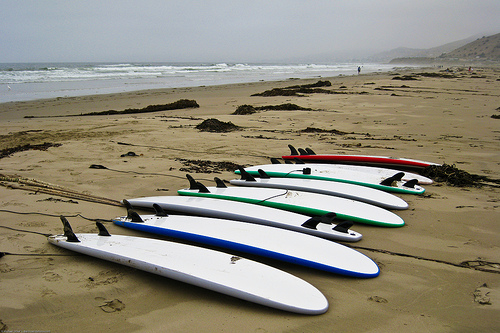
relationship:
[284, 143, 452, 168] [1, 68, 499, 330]
surfboard on beach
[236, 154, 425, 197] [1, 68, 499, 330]
surfboard on beach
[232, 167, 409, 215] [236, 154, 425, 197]
surfboard next to surfboard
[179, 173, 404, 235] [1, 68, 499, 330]
surfboard on beach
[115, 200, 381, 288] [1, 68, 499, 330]
surfboard on sand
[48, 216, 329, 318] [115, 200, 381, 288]
surfboard next to surfboard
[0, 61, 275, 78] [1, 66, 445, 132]
wave near shore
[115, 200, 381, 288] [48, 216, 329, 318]
surfboard next to surfboard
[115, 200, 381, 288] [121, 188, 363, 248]
surfboard next to surfboard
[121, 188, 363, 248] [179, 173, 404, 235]
surfboard next to surfboard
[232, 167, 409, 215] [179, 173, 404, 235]
surfboard next to surfboard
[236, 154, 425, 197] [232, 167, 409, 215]
surfboard next to surfboard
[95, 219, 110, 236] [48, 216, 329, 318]
knob on surfboard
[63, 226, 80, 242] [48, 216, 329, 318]
knob on surfboard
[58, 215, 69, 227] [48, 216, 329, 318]
knob on surfboard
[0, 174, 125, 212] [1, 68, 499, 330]
tracks on beach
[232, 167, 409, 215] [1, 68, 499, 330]
surfboard on beach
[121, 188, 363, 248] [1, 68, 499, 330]
surfboard on beach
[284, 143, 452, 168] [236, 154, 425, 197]
surfboard beside surfboard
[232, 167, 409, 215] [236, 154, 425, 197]
surfboard beside surfboard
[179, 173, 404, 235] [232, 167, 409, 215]
surfboard beside surfboard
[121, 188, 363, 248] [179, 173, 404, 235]
surfboard beside surfboard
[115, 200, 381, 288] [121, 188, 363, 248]
surfboard beside surfboard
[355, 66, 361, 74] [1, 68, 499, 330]
person on beach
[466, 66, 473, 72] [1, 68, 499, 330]
person on beach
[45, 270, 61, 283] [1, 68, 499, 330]
footprint on beach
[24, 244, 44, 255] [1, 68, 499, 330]
footprint on beach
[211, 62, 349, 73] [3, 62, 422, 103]
wave on water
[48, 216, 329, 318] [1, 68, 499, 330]
surfboard on beach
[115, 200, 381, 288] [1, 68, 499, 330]
surfboard on beach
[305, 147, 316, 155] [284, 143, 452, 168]
fin on surfboard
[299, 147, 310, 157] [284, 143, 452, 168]
fin on surfboard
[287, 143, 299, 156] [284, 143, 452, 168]
fin on surfboard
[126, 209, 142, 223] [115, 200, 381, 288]
fin on surfboard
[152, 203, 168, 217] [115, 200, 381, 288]
fin on surfboard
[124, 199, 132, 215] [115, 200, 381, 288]
fin on surfboard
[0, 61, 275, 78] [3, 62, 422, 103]
wave on water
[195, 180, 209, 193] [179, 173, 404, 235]
fin on surfboard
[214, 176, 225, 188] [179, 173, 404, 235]
fin on surfboard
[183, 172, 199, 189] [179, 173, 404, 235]
fin on surfboard